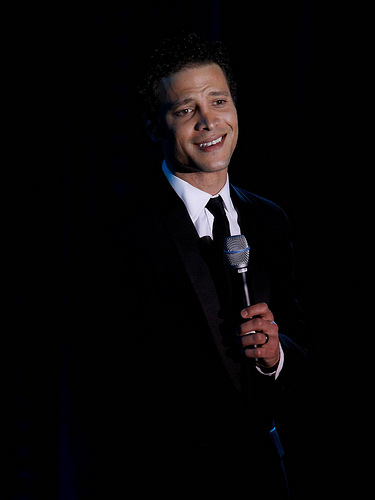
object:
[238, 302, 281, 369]
hand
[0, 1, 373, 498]
background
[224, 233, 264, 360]
mic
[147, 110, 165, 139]
ear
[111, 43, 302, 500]
man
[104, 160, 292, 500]
suit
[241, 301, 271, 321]
finger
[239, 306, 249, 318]
fingernail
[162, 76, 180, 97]
vein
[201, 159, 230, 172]
chin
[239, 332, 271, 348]
finger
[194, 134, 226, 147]
teeth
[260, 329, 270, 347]
ring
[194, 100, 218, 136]
man's nose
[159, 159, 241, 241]
shirt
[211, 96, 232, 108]
eyes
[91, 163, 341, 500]
coat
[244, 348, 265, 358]
fingers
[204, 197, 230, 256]
tie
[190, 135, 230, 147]
mouth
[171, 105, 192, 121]
eye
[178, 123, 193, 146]
cheek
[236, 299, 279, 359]
hands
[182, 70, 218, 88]
forehead